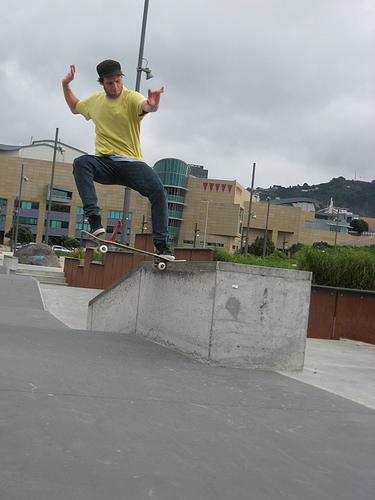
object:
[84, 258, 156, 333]
ramp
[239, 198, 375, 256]
buildings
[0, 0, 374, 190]
sky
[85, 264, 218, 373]
wall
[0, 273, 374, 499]
path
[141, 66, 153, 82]
light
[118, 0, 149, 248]
pole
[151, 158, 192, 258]
building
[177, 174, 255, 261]
building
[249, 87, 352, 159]
air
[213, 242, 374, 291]
shrubbery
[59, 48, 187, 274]
midair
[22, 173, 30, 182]
light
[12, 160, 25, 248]
pole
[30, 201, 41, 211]
windows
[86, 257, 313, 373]
block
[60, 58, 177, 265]
man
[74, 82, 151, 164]
shirt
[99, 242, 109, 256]
wheels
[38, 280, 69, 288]
steps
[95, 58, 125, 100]
head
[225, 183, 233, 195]
triangles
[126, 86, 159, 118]
arms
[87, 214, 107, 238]
sneakers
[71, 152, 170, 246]
jeans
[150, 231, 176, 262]
high tops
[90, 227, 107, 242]
soles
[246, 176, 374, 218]
hills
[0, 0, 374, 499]
background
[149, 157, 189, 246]
center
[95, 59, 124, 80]
hat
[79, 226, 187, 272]
skateboard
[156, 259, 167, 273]
wheels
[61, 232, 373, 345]
wall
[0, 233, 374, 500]
skate park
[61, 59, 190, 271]
trick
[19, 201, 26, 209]
window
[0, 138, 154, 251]
building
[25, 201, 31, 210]
window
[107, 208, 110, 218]
window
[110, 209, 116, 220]
window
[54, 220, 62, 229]
window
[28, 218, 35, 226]
window